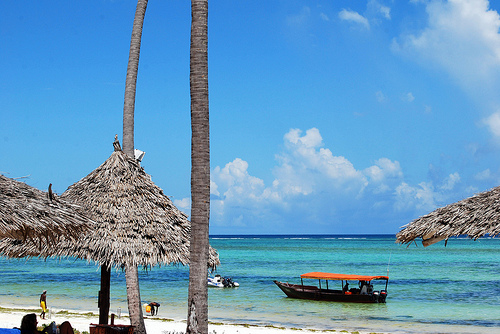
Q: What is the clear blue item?
A: Ocean.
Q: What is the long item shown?
A: Tree trunk.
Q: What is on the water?
A: Boat.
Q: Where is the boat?
A: Water.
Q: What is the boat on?
A: Water.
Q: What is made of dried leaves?
A: A roof.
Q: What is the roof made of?
A: Dried leaves.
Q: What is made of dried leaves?
A: Roof.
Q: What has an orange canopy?
A: Boat.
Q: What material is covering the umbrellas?
A: Thatch.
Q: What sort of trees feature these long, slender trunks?
A: Palm trees.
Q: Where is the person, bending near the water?
A: At the water's edge, visible between the two palm trees.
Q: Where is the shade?
A: In the space covered by the two, touching umbrellas.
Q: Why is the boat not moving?
A: The water it is in is too calm and too shallow.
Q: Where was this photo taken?
A: The beach.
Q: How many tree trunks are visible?
A: Two.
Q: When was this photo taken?
A: Outside, during the daytime.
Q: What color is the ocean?
A: Blue.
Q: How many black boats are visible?
A: One.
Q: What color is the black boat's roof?
A: Orange.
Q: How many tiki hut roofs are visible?
A: Three.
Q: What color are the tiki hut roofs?
A: Brown.